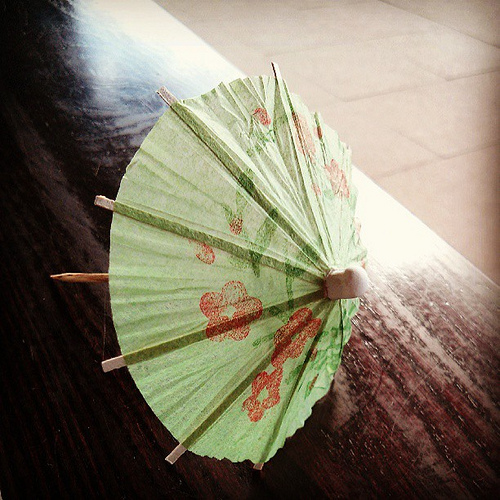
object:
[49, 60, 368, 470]
umbrella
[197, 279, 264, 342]
flowers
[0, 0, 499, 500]
table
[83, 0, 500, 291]
light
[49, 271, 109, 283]
stake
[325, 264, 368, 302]
knob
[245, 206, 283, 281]
leaf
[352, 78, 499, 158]
tile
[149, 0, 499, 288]
floor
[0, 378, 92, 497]
lines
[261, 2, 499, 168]
lines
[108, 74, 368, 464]
paper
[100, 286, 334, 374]
ribs